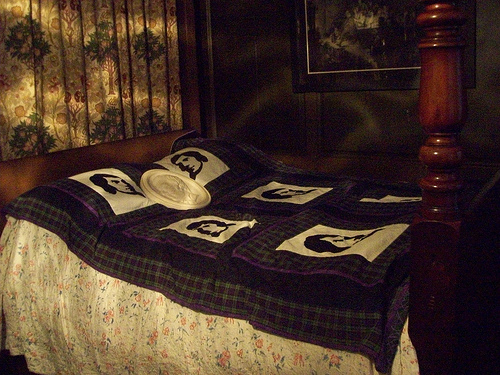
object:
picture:
[68, 168, 153, 217]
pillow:
[6, 162, 169, 233]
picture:
[154, 147, 231, 189]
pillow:
[157, 131, 279, 196]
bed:
[1, 128, 460, 374]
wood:
[411, 1, 464, 375]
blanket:
[0, 141, 412, 369]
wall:
[195, 1, 305, 154]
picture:
[304, 1, 425, 74]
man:
[172, 148, 212, 178]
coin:
[139, 164, 211, 209]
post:
[409, 1, 468, 375]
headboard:
[410, 171, 497, 373]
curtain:
[1, 0, 183, 152]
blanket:
[1, 217, 421, 375]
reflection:
[432, 136, 441, 162]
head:
[156, 175, 200, 205]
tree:
[84, 19, 126, 95]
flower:
[216, 350, 233, 369]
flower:
[100, 307, 117, 321]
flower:
[76, 259, 89, 273]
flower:
[288, 351, 308, 367]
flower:
[18, 246, 30, 258]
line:
[303, 1, 311, 76]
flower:
[143, 325, 176, 349]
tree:
[130, 24, 166, 65]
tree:
[5, 15, 49, 71]